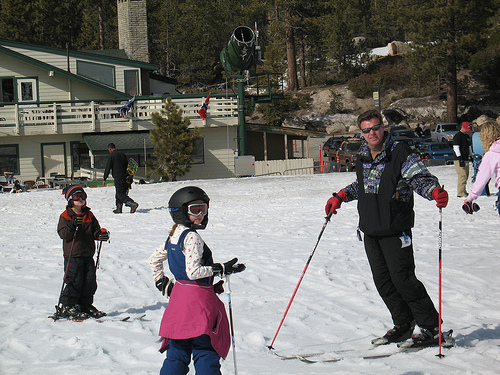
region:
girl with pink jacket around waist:
[170, 278, 221, 334]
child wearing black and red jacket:
[56, 211, 104, 239]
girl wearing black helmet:
[170, 184, 212, 232]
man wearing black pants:
[362, 227, 432, 325]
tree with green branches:
[145, 96, 195, 176]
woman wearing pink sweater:
[463, 142, 498, 192]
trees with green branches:
[412, 47, 484, 87]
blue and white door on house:
[12, 73, 42, 100]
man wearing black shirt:
[102, 151, 128, 177]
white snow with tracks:
[11, 202, 48, 332]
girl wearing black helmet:
[142, 176, 257, 368]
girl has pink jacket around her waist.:
[135, 164, 246, 374]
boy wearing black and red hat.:
[40, 150, 118, 334]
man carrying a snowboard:
[95, 120, 148, 220]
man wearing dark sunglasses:
[308, 79, 471, 365]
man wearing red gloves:
[303, 52, 476, 368]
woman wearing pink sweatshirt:
[462, 104, 498, 219]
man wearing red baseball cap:
[448, 105, 475, 208]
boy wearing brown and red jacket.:
[45, 140, 112, 347]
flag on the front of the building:
[191, 85, 218, 126]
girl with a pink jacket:
[141, 169, 271, 374]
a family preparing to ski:
[37, 101, 452, 358]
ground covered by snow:
[223, 173, 312, 250]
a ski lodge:
[1, 38, 329, 188]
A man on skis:
[275, 107, 457, 373]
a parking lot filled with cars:
[320, 108, 470, 168]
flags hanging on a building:
[107, 92, 232, 127]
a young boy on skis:
[37, 177, 136, 328]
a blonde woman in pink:
[460, 113, 499, 195]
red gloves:
[315, 177, 464, 220]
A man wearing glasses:
[341, 105, 404, 164]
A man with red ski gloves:
[325, 99, 462, 279]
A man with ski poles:
[284, 100, 454, 371]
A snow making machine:
[204, 8, 279, 113]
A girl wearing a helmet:
[152, 175, 212, 247]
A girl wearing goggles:
[160, 185, 222, 241]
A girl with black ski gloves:
[147, 180, 263, 302]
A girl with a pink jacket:
[133, 190, 261, 362]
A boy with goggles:
[48, 171, 107, 276]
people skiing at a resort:
[32, 102, 498, 373]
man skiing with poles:
[262, 107, 455, 372]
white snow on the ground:
[246, 181, 296, 258]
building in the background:
[2, 31, 262, 197]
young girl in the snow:
[137, 179, 259, 374]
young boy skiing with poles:
[39, 172, 118, 332]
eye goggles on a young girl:
[180, 200, 217, 218]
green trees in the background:
[254, 5, 495, 42]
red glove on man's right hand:
[310, 182, 350, 225]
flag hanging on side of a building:
[187, 88, 224, 124]